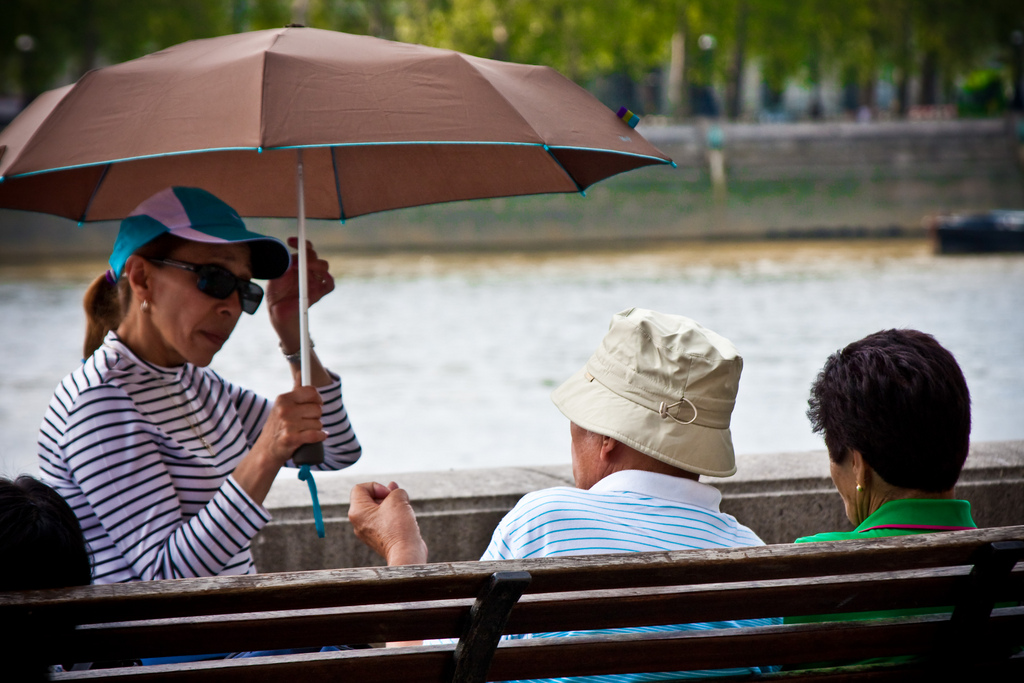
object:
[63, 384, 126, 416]
stripe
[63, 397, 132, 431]
stripe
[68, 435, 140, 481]
stripe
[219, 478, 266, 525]
stripe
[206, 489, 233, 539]
stripe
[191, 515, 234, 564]
stripe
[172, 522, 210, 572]
stripe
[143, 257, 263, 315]
glasses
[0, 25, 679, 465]
umbrella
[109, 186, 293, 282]
hat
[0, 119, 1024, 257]
wall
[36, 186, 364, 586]
woman